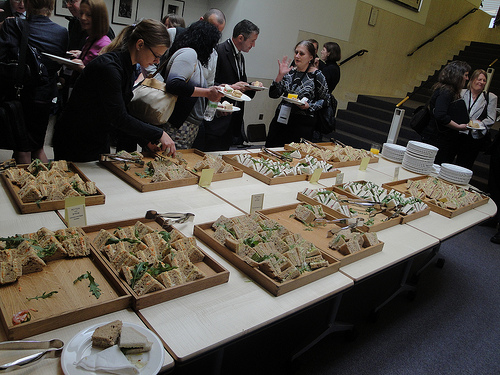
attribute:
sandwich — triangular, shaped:
[261, 258, 282, 279]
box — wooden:
[2, 159, 106, 214]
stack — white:
[382, 142, 406, 164]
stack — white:
[402, 139, 438, 175]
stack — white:
[438, 163, 473, 187]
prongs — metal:
[146, 210, 196, 226]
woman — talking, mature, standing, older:
[265, 42, 331, 146]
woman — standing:
[410, 60, 487, 142]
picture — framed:
[160, 1, 185, 22]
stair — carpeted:
[451, 40, 499, 61]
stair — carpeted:
[346, 91, 391, 112]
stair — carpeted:
[339, 119, 384, 147]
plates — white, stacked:
[431, 164, 441, 176]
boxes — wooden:
[104, 149, 245, 192]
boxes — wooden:
[1, 214, 230, 341]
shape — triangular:
[21, 252, 47, 274]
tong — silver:
[1, 339, 65, 373]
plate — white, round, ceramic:
[61, 319, 165, 374]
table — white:
[248, 137, 499, 242]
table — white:
[2, 170, 176, 372]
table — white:
[57, 154, 354, 364]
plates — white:
[382, 139, 473, 186]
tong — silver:
[100, 154, 143, 163]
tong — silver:
[261, 146, 295, 164]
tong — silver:
[300, 136, 329, 153]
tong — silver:
[332, 135, 348, 148]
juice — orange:
[370, 146, 381, 154]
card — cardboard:
[64, 197, 88, 229]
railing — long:
[340, 8, 479, 65]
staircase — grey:
[339, 94, 383, 139]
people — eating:
[4, 1, 337, 143]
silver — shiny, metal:
[101, 149, 195, 231]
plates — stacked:
[380, 141, 407, 162]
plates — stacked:
[399, 139, 438, 176]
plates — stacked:
[435, 158, 478, 187]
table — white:
[4, 134, 488, 371]